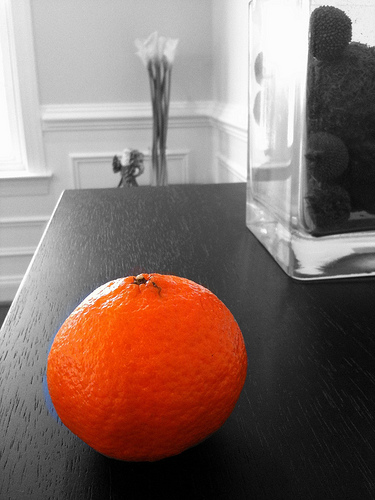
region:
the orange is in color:
[35, 257, 293, 431]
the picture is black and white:
[24, 0, 356, 269]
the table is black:
[226, 312, 345, 473]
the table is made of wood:
[231, 313, 347, 469]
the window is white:
[2, 4, 50, 200]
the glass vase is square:
[211, 1, 371, 295]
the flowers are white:
[92, 19, 203, 178]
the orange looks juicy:
[21, 251, 265, 461]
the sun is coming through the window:
[1, 102, 40, 172]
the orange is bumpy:
[27, 254, 258, 448]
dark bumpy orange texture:
[104, 361, 158, 406]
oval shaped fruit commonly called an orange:
[43, 265, 256, 464]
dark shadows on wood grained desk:
[267, 347, 357, 473]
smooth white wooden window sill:
[2, 169, 55, 197]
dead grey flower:
[303, 8, 352, 61]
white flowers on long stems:
[131, 32, 184, 188]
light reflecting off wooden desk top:
[6, 255, 59, 330]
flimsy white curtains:
[5, 82, 28, 173]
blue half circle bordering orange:
[40, 301, 87, 486]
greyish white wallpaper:
[47, 19, 124, 92]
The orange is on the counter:
[29, 257, 262, 463]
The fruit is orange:
[35, 255, 257, 458]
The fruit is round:
[42, 240, 260, 468]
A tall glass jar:
[234, 9, 362, 280]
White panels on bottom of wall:
[38, 66, 239, 194]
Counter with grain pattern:
[13, 175, 367, 473]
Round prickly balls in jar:
[260, 7, 361, 227]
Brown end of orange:
[121, 265, 168, 293]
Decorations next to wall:
[112, 27, 198, 189]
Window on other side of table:
[1, 13, 69, 206]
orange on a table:
[63, 254, 291, 463]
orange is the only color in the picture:
[47, 309, 305, 499]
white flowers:
[148, 27, 205, 184]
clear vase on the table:
[231, 20, 368, 282]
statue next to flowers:
[82, 132, 164, 188]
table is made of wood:
[104, 186, 299, 249]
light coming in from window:
[5, 11, 34, 170]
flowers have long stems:
[136, 61, 197, 180]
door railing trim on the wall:
[64, 86, 261, 138]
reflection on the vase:
[281, 28, 312, 183]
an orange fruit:
[96, 258, 256, 498]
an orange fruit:
[130, 313, 235, 475]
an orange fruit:
[79, 295, 208, 478]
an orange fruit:
[52, 430, 202, 491]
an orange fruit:
[66, 206, 201, 436]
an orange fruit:
[90, 240, 171, 459]